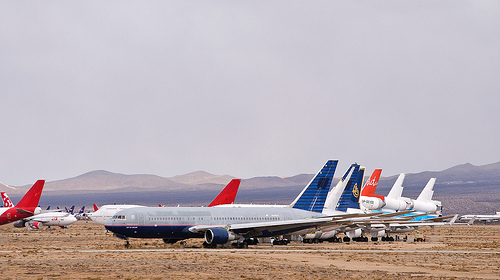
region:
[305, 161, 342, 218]
the tail is blue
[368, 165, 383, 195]
the tail is red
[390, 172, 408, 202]
the tail is white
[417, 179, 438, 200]
the tail is white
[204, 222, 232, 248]
the engine is blue in color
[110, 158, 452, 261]
the planes are parked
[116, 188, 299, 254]
the plane is grey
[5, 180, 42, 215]
the tail is red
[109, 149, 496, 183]
hills are in the background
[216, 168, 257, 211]
the tail is red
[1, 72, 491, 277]
The planes are out in the desert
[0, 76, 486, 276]
The plans are in a desert location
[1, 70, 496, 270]
The planes are carrying many passengers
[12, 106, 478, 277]
The planes belong to the airlines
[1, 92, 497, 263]
The planes have landed safely today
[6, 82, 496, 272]
The planes are being safely refueled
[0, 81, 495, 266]
The planes are under the sunshine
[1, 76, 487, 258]
The planes are all lined up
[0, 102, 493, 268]
The planes have good safety records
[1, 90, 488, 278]
The aircraft are all passenger planes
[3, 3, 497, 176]
pale blue of sky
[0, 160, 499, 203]
hazy mountains on horizon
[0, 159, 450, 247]
planes parked on desert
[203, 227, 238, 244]
blue engine under wing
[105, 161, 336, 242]
blue and gray body of plane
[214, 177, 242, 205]
red tail of plane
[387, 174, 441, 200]
two white tails of planes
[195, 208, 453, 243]
wings on side of plane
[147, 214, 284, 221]
row of windows on plane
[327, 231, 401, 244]
wheels of landing gear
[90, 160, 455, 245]
parked airplanes overlapping each other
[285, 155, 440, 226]
airplanes with red, white and blue tails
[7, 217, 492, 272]
flat and rough brown ground under planes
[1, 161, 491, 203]
border of low mountains in earthy hues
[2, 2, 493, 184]
solid gray sky over mountains and planes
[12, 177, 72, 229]
small white plane behind red tail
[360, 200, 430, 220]
aqua blue stripe broken up by planes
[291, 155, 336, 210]
black square on blue and black horizontal stripes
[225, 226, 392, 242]
line of black wheels under planes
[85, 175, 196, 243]
thin red line dividing top and bottom of plane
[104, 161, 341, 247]
a gray and blue airplane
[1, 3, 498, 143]
a vast sky in the background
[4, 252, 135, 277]
brown dirt on the ground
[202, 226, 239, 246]
jet engine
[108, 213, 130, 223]
windows on a plane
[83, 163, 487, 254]
a bunch of parked planes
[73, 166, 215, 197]
hills in the distance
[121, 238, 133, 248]
a wheel on the plane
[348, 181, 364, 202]
a logo on a plane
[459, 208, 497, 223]
a white plane